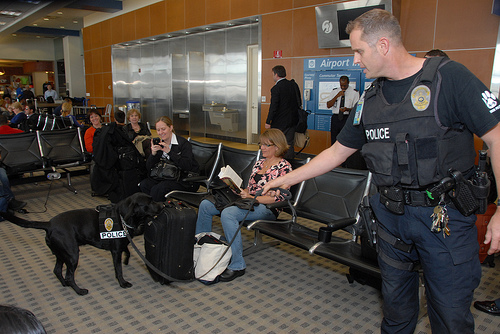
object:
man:
[253, 7, 500, 334]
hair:
[344, 8, 404, 47]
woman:
[193, 127, 293, 282]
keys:
[430, 201, 451, 238]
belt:
[404, 186, 444, 206]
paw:
[119, 281, 133, 289]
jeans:
[194, 200, 277, 271]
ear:
[379, 37, 390, 55]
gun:
[354, 197, 377, 246]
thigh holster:
[352, 195, 377, 250]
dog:
[0, 192, 165, 297]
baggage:
[142, 199, 232, 287]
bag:
[193, 232, 233, 286]